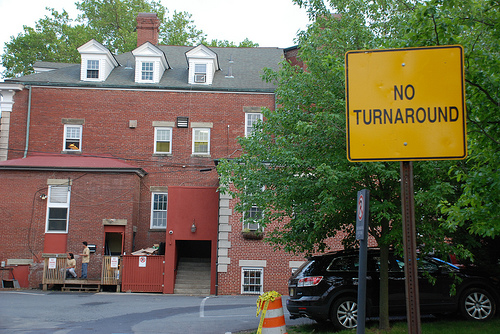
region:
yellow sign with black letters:
[341, 30, 474, 170]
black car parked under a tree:
[279, 206, 495, 319]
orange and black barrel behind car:
[246, 289, 304, 328]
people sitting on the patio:
[18, 242, 123, 283]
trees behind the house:
[11, 0, 211, 85]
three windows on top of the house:
[15, 31, 256, 86]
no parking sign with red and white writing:
[340, 188, 375, 259]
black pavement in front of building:
[8, 292, 255, 327]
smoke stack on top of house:
[115, 5, 172, 53]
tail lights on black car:
[287, 267, 335, 297]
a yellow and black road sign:
[341, 45, 474, 163]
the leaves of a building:
[286, 89, 325, 161]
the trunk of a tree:
[376, 241, 392, 332]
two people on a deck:
[61, 239, 96, 283]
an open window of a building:
[56, 122, 85, 153]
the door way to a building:
[168, 235, 215, 298]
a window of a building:
[42, 179, 74, 236]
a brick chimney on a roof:
[132, 12, 163, 47]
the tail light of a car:
[294, 271, 328, 289]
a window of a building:
[239, 258, 266, 294]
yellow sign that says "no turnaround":
[347, 43, 463, 331]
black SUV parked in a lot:
[289, 246, 496, 323]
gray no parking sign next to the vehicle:
[355, 185, 368, 329]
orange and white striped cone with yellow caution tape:
[256, 289, 285, 332]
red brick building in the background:
[0, 13, 384, 298]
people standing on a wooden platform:
[66, 238, 91, 275]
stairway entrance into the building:
[173, 242, 213, 294]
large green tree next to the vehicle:
[222, 0, 498, 280]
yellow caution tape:
[253, 287, 279, 329]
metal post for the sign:
[405, 160, 419, 332]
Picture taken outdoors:
[21, 11, 372, 326]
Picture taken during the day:
[35, 25, 482, 331]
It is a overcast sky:
[221, 14, 293, 45]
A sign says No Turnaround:
[349, 46, 461, 153]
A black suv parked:
[275, 223, 460, 330]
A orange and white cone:
[262, 296, 284, 328]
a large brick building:
[0, 104, 255, 291]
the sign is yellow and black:
[348, 52, 470, 159]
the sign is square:
[323, 43, 467, 163]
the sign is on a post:
[398, 164, 439, 326]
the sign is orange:
[327, 43, 477, 163]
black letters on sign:
[342, 61, 471, 137]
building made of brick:
[12, 79, 320, 292]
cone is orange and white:
[245, 281, 312, 332]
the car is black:
[282, 218, 499, 332]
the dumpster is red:
[117, 237, 165, 299]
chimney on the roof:
[131, 1, 173, 55]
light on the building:
[166, 105, 192, 132]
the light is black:
[166, 110, 197, 136]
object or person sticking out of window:
[55, 131, 88, 155]